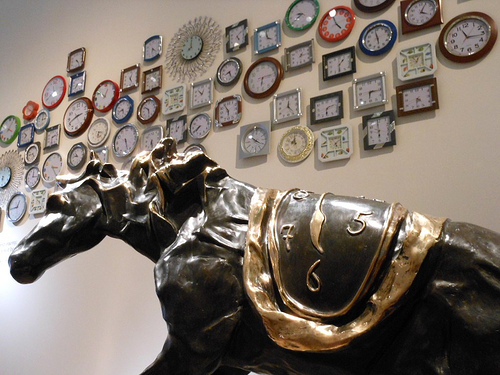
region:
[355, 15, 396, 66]
a blue clock on the wall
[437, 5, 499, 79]
a brown clock the wall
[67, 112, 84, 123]
dials on a clock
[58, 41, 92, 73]
a square clock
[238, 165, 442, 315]
numbers on the horse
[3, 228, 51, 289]
nose of the horse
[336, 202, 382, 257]
the number 5 on saddle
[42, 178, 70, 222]
eye of the horse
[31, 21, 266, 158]
many clocks on wall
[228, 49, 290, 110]
round clock on wall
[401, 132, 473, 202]
white wall in room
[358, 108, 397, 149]
Clock hung on the white wall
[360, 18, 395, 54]
Blue clock hung on the white wall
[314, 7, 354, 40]
Orange clock hung on the white wall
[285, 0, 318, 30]
Green clock hung on the white wall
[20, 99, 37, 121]
Flower clock hung on the white wall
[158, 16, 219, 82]
Clock hung on the white wall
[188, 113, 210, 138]
Clock hung on the white wall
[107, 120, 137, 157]
Clock hung on the white wall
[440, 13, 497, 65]
Clock hung on the white wall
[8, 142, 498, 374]
Horse sculpture in front of white wall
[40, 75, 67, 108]
white analog clock in red frame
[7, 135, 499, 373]
shiny statue of a horse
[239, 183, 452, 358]
melted gold clock on a statue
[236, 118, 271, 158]
silver square framed clock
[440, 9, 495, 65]
circular clock with wood frame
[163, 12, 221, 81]
shiny sun shaped analog clock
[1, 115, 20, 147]
white analog clock with green frame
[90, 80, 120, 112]
white analog clock with red frame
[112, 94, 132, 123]
white analog clock with blue frame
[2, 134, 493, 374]
a wooden horse sculpture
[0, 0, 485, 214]
a bunch of small clocks on a wall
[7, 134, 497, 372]
a fake horse with a clock on its back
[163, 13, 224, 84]
a clock shaped like a sun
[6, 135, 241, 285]
the head and mane of a wooden horse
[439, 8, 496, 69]
a brown circular clock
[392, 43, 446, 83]
bizarre square shaped clock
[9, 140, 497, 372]
a bronze statue of a horse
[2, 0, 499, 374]
a room with clock centric knick knacks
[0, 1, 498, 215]
a variety of different clock shapes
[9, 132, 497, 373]
A large horse statue.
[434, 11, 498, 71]
A round clock mounted to a wall.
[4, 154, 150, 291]
The head of a horse statue.